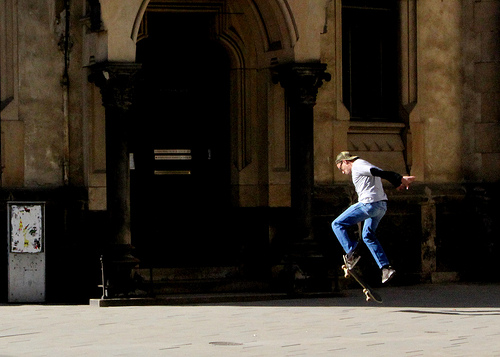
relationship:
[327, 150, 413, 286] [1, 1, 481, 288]
man riding in front of building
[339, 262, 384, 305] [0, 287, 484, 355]
skateboard flying above ground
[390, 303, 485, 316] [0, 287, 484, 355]
shadow casted on ground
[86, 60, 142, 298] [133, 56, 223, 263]
column standing next to door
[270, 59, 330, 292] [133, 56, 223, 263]
column standing next to door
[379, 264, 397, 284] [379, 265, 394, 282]
shoe covering foot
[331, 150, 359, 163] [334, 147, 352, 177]
hat worn on head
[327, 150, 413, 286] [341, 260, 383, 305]
man on skateboard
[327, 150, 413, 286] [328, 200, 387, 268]
man wearing jeans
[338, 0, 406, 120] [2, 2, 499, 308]
window on building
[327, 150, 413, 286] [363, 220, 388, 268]
man has leg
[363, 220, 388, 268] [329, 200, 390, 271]
leg in jeans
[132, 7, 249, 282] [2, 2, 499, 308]
door on building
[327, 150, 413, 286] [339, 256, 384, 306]
man on skateboard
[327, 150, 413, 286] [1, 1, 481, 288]
man in front of building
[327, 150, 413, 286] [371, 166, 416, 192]
man has arms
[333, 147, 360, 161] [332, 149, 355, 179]
hat on head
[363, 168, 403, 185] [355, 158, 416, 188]
sleeves on arm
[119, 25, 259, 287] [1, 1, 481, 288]
doorway of building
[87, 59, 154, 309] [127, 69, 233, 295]
column in front of door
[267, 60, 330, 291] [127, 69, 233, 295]
column in front of door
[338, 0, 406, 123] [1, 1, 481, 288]
window on building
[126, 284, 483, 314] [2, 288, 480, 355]
shadow on surface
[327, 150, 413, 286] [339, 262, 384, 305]
man leaping with skateboard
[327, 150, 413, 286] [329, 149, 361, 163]
man in hat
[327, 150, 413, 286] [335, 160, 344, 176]
man with shades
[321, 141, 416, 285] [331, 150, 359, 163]
man in hat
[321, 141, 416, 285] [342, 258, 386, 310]
man riding skateboard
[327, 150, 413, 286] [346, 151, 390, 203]
man in shirt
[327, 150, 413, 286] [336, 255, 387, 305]
man with skateboard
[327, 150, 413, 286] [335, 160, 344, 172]
man in shades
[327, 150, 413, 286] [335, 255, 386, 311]
man flipping skateboard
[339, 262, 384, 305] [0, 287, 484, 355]
skateboard coming off ground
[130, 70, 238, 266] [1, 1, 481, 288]
entrance to building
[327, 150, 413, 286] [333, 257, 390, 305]
man jumping on skateboard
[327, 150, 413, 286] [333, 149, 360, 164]
man wearing hat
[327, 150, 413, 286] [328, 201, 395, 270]
man wearing jeans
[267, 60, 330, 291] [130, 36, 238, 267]
column at entrance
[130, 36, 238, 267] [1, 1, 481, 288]
entrance of building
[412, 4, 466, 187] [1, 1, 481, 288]
wall of building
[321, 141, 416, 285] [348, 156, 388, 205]
man wears shirt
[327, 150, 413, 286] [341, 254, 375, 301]
man over skateboard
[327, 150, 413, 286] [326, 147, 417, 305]
man does skate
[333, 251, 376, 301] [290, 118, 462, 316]
skateboard in air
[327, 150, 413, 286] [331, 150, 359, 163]
man wears hat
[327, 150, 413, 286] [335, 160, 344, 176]
man wears shades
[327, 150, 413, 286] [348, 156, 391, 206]
man wears shirt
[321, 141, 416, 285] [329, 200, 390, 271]
man wears jeans